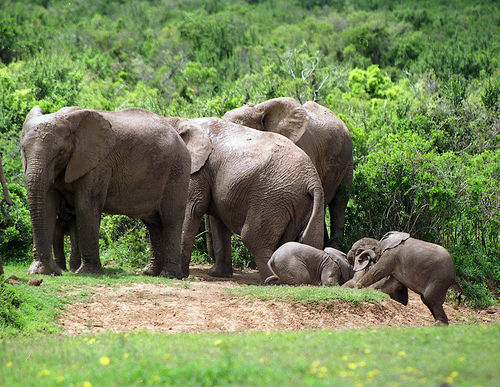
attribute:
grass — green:
[158, 336, 193, 348]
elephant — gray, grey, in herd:
[20, 104, 185, 281]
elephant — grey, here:
[165, 114, 324, 278]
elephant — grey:
[223, 93, 350, 245]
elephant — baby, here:
[356, 233, 454, 325]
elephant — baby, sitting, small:
[265, 240, 357, 288]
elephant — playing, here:
[344, 238, 406, 305]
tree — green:
[348, 118, 441, 227]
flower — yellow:
[99, 355, 110, 364]